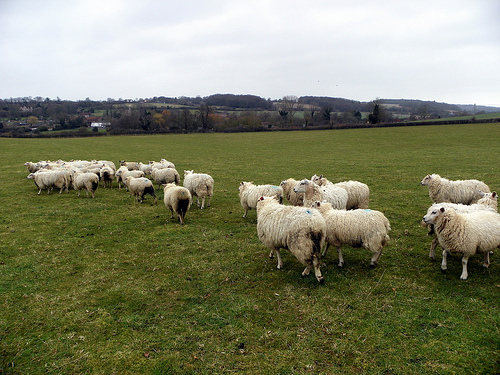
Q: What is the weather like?
A: It is cloudy.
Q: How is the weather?
A: It is cloudy.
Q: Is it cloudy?
A: Yes, it is cloudy.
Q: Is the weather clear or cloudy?
A: It is cloudy.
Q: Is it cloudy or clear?
A: It is cloudy.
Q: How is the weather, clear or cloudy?
A: It is cloudy.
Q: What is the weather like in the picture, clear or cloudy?
A: It is cloudy.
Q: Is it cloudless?
A: No, it is cloudy.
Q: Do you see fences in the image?
A: No, there are no fences.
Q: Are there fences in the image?
A: No, there are no fences.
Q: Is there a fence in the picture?
A: No, there are no fences.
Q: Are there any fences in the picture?
A: No, there are no fences.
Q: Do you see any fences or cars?
A: No, there are no fences or cars.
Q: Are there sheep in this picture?
A: Yes, there is a sheep.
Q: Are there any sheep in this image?
A: Yes, there is a sheep.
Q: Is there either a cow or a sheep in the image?
A: Yes, there is a sheep.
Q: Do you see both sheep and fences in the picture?
A: No, there is a sheep but no fences.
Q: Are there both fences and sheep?
A: No, there is a sheep but no fences.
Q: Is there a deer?
A: No, there is no deer.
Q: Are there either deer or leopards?
A: No, there are no deer or leopards.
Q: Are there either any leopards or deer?
A: No, there are no deer or leopards.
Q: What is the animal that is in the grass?
A: The animal is a sheep.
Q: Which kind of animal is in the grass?
A: The animal is a sheep.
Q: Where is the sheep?
A: The sheep is in the grass.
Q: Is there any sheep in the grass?
A: Yes, there is a sheep in the grass.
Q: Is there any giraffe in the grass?
A: No, there is a sheep in the grass.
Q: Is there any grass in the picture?
A: Yes, there is grass.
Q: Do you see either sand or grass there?
A: Yes, there is grass.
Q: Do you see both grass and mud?
A: No, there is grass but no mud.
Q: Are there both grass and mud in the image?
A: No, there is grass but no mud.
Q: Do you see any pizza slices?
A: No, there are no pizza slices.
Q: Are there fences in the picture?
A: No, there are no fences.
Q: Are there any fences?
A: No, there are no fences.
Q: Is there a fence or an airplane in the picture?
A: No, there are no fences or airplanes.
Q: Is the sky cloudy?
A: Yes, the sky is cloudy.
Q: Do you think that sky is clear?
A: No, the sky is cloudy.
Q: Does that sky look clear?
A: No, the sky is cloudy.